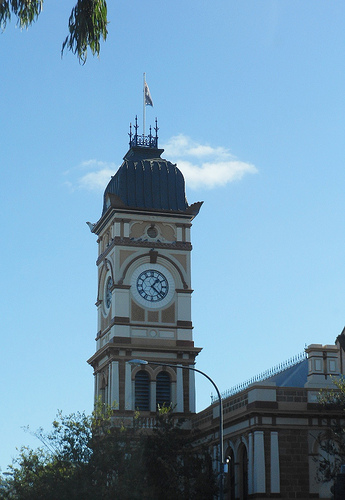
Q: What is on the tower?
A: Clock.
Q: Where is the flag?
A: Top of tower.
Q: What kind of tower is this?
A: Clock tower.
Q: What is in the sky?
A: Cloud.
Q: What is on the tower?
A: A clock.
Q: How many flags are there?
A: 1.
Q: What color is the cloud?
A: White.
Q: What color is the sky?
A: Blue.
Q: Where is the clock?
A: On top of the steeple.